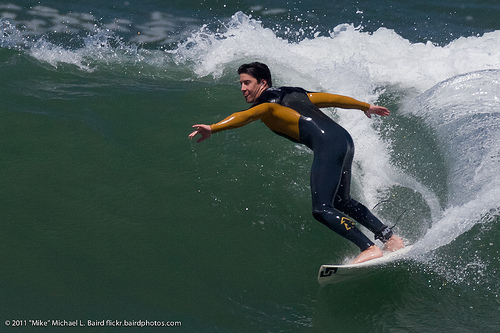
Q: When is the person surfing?
A: Daytime.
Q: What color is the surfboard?
A: White.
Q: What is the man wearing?
A: A wetsuit.